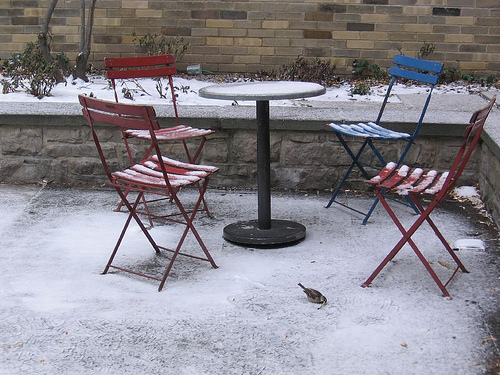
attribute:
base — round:
[224, 216, 311, 248]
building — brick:
[5, 0, 496, 78]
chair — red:
[327, 38, 440, 243]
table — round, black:
[198, 79, 325, 247]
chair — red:
[77, 93, 222, 291]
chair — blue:
[330, 55, 425, 215]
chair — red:
[83, 97, 215, 279]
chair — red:
[101, 51, 211, 218]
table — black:
[195, 65, 332, 264]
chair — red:
[72, 91, 211, 282]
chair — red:
[110, 42, 217, 147]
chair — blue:
[323, 51, 443, 160]